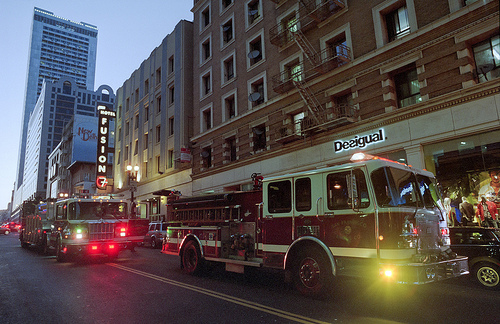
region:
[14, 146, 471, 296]
two red and white fire trucks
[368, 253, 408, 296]
yellow light on fire truck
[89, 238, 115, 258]
two red lights on a fire truck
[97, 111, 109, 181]
white text on a black sign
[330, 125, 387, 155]
black text on a cement building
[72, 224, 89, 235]
a green light on a fire truck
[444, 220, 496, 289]
black vehicle parked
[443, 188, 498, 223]
clothing store display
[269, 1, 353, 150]
metal fire exit stairs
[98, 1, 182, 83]
grey sky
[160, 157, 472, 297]
a fire truck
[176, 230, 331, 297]
the wheels of a fire truck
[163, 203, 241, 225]
the ladder of a fire truck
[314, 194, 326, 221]
the door handle of a fire truck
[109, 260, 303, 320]
the divider line in the street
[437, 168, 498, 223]
a store window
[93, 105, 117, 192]
s brightly lit sign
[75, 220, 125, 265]
the headlights on a fire truck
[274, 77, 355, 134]
the fire escape ladder of a building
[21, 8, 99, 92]
a tall building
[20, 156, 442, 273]
these are fire fighters engines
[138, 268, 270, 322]
two yellow strips are drawn on the road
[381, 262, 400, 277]
the side light is on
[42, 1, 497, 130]
these are buildings beside the road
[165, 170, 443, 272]
the fire brigade engine is red in color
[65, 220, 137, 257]
the front lights are on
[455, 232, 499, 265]
a car is parked beside the fire brigade engine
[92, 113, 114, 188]
the post is written fusion 7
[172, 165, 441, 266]
this fire brigade is big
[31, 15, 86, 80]
the building is tall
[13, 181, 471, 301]
Two red fire trucks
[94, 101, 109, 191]
Fusion sign in front of the building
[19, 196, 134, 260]
Lights on a fire truck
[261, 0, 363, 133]
Fire escapes on the apartment building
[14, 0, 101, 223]
A tall building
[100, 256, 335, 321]
Yellow solid street divider line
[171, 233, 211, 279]
A fire truck wheel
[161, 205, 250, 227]
A fire truck ladder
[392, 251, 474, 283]
A fire truck's bumper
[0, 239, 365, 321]
The street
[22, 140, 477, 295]
fire engines moving down a street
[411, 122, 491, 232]
shop window filled with clothing and mannequins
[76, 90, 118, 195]
large lit sign attached to building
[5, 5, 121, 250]
towering building at end of the street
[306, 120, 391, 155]
sign lit from behind over store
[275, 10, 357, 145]
fire escape crossing in front of windows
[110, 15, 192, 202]
building with vertical stripes between windows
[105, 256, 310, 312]
street divided by double yellow line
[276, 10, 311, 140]
three lit windows on different floors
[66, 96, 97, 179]
large advertisement on side of building